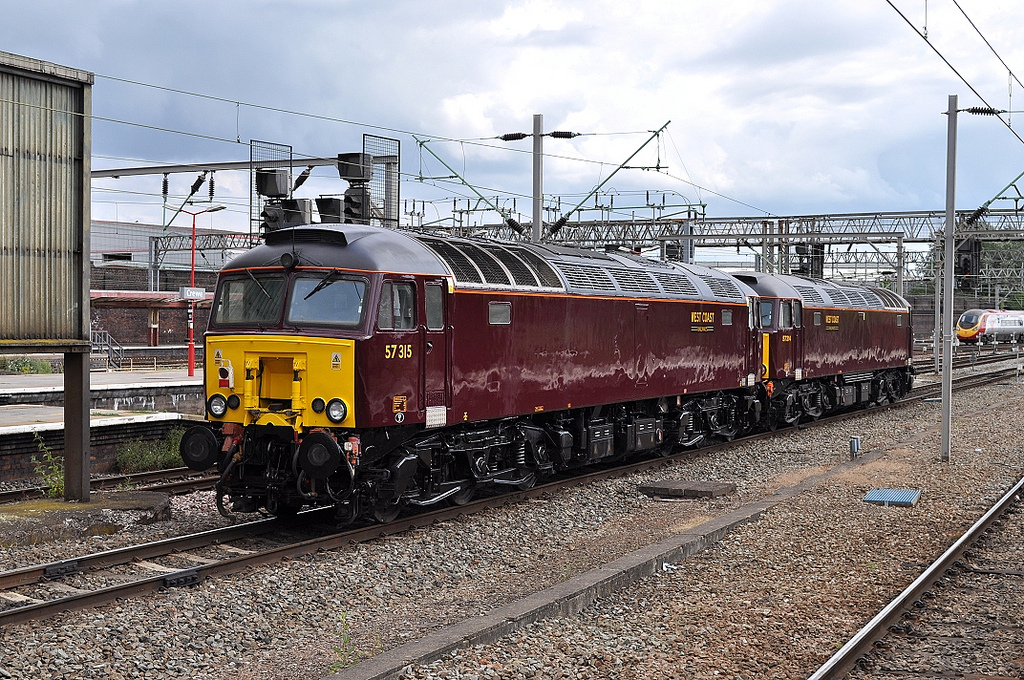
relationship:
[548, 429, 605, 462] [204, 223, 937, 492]
wheel on train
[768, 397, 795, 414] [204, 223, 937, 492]
wheel on train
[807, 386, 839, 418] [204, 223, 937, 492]
wheel on train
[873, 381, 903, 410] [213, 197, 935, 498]
wheel on train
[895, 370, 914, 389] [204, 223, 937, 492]
wheel on train